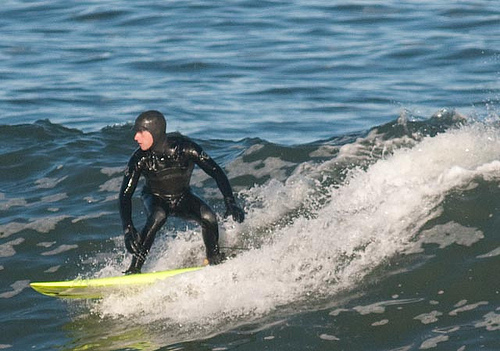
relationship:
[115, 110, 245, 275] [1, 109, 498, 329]
man riding on wave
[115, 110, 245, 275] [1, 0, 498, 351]
man surfing in ocean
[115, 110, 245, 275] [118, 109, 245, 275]
man wearing wetsuit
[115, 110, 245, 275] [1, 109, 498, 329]
man surfing on wave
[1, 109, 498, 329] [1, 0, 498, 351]
wave part of ocean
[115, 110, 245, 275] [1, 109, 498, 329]
man balancing on wave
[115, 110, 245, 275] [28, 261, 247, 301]
man on top of surfboard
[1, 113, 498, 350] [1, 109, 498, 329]
foam on top of wave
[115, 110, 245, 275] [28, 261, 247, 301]
man standing on surfboard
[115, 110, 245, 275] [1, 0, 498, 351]
man surfing on ocean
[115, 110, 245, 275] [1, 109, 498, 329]
man on top of wave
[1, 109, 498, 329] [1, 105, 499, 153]
wave has crest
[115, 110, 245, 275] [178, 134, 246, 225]
man has arm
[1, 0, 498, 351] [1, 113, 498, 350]
ocean has foam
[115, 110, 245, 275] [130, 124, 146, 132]
man has hair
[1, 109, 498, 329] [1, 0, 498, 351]
wave on top of ocean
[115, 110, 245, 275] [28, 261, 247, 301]
man balancing on surfboard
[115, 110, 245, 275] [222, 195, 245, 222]
man wearing glove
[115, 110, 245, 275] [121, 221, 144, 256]
man wearing glove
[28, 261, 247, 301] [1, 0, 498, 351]
surfboard on top of ocean